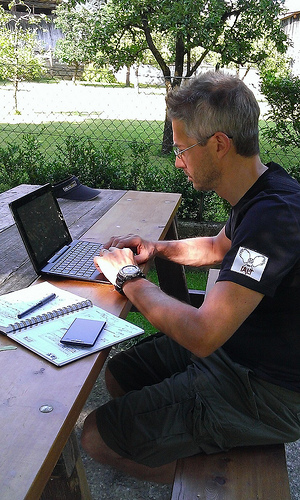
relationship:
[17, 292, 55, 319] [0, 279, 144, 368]
pen on book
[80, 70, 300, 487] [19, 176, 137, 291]
he working on laptop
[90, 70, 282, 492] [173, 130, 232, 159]
he wearing glasses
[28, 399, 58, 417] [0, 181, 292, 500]
bolt in picnic table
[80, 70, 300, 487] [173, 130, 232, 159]
he wearing glasses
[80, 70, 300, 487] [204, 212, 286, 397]
he wearing shirt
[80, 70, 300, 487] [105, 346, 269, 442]
he wearing shorts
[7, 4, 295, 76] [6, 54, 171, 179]
trees beside fence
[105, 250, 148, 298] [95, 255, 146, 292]
watch on wrist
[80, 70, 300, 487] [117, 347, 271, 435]
he wearing shorts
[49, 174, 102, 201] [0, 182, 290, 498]
black visor on picnic table